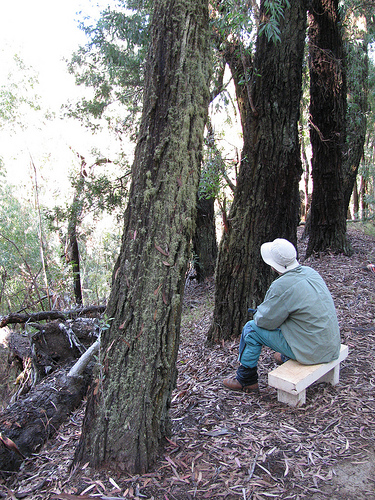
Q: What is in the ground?
A: Dried leaves.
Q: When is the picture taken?
A: Daytime.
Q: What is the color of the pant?
A: Blue.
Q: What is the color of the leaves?
A: Green.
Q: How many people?
A: 1.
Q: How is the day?
A: Sunny.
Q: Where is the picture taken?
A: On a nature trail.